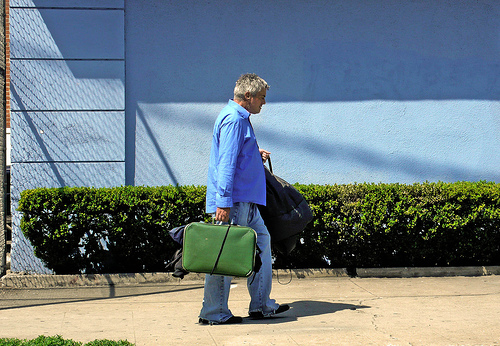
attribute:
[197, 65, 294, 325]
man — gray, walking, alone, pacing, old, untucked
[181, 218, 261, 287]
suitcase — green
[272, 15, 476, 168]
wall — blue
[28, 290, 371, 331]
sidewalk — cracked, white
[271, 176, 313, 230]
bag — blue, loose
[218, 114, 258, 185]
shirt — blue